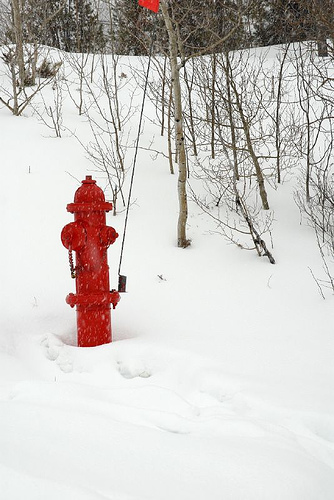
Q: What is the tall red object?
A: A fire hydrant.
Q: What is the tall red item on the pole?
A: A flat.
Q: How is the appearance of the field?
A: Snowy.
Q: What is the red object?
A: Fire hydrant.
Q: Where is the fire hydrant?
A: Snow.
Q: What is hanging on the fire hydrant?
A: Chain.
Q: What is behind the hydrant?
A: Trees.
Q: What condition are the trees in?
A: Bare leafless branches.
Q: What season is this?
A: Winter.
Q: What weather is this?
A: Snow.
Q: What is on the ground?
A: Snow.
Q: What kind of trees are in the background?
A: Pine trees.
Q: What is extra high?
A: A fire hydrant.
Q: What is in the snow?
A: Deep footprints.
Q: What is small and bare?
A: Stick trees.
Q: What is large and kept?
A: Pine trees.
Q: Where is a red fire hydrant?
A: In the snow.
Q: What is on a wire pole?
A: A flag.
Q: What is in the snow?
A: Bare trees.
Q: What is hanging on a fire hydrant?
A: A chain.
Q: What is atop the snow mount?
A: Gray skys.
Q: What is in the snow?
A: Fire hydrant.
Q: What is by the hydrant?
A: Food prints.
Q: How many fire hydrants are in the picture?
A: 1.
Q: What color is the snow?
A: White.